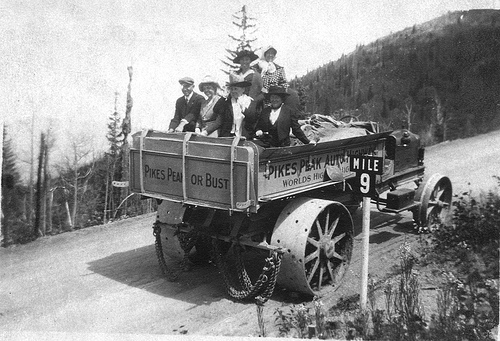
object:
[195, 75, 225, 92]
white hat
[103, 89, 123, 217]
tree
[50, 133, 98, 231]
tree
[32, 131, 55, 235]
tree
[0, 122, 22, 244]
tree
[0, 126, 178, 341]
roadside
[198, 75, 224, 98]
person's head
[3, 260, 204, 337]
road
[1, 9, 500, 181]
mountains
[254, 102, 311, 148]
jacket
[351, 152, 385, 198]
sign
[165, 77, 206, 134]
man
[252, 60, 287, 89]
dress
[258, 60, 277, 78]
bow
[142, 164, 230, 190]
sign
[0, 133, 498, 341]
dirt road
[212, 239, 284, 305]
chain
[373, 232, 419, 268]
ground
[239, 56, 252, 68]
head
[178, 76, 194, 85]
cap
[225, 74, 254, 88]
hat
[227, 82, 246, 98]
head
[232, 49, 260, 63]
bonnet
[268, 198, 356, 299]
truck wheel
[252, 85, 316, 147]
woman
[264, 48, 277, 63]
head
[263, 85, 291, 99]
hat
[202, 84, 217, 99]
head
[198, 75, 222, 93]
cap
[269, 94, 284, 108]
head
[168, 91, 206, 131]
jacket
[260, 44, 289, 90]
person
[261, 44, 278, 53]
bonnet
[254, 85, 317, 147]
person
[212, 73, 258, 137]
person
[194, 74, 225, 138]
person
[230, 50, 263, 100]
person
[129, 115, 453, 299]
truck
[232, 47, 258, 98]
woman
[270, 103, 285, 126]
shirt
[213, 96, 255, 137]
jacket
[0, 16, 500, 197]
terrain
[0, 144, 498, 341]
road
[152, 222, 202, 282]
chains